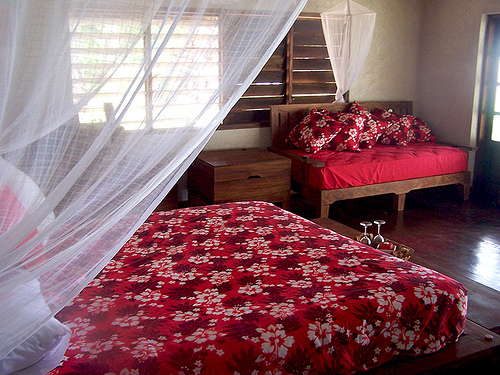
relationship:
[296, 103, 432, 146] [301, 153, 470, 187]
pillows on couch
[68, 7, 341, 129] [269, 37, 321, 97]
blinds has blinds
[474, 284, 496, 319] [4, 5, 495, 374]
bench in room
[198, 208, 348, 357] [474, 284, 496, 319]
matress on top of bench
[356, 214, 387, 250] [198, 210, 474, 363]
wine glasses at foot of bed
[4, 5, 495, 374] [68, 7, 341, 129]
room has blinds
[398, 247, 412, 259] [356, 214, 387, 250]
basket of wine glasses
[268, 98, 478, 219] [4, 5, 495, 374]
couch in room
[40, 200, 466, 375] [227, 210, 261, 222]
bed spread has flowers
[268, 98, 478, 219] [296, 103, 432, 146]
couch has pillows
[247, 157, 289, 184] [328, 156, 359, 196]
dresser next to soffa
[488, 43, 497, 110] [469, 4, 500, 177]
light coming in door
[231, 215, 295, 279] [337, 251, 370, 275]
bed spread has floral print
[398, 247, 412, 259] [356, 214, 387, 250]
basket has wine glasses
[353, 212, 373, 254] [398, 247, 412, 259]
wineglass in basket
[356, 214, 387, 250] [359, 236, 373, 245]
wine glasses upside down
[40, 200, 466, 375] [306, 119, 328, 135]
bed spread has flower pattern